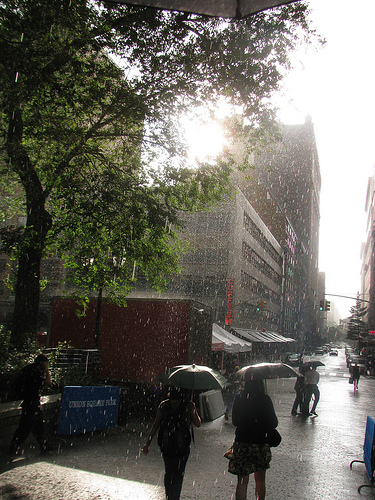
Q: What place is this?
A: It is a sidewalk.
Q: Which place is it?
A: It is a sidewalk.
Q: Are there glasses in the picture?
A: No, there are no glasses.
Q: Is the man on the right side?
A: Yes, the man is on the right of the image.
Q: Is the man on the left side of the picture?
A: No, the man is on the right of the image.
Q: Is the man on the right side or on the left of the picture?
A: The man is on the right of the image.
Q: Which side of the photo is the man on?
A: The man is on the right of the image.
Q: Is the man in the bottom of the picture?
A: Yes, the man is in the bottom of the image.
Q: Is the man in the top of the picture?
A: No, the man is in the bottom of the image.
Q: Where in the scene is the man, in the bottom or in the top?
A: The man is in the bottom of the image.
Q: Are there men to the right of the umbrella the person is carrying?
A: Yes, there is a man to the right of the umbrella.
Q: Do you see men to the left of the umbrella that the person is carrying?
A: No, the man is to the right of the umbrella.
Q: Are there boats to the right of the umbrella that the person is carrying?
A: No, there is a man to the right of the umbrella.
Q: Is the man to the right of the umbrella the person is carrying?
A: Yes, the man is to the right of the umbrella.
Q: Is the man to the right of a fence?
A: No, the man is to the right of the umbrella.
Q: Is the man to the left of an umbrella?
A: No, the man is to the right of an umbrella.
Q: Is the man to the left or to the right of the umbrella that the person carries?
A: The man is to the right of the umbrella.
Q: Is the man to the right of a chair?
A: No, the man is to the right of the umbrella.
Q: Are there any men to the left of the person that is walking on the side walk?
A: Yes, there is a man to the left of the person.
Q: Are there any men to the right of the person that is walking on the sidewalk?
A: No, the man is to the left of the person.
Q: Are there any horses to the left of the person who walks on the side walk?
A: No, there is a man to the left of the person.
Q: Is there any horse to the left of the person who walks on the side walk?
A: No, there is a man to the left of the person.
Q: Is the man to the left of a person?
A: Yes, the man is to the left of a person.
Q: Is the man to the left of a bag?
A: No, the man is to the left of a person.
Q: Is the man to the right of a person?
A: No, the man is to the left of a person.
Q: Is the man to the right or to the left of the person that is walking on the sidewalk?
A: The man is to the left of the person.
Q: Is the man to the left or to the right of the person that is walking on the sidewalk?
A: The man is to the left of the person.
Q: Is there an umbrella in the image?
A: Yes, there is an umbrella.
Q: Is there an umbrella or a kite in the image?
A: Yes, there is an umbrella.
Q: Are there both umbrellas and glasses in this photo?
A: No, there is an umbrella but no glasses.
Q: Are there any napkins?
A: No, there are no napkins.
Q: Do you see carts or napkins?
A: No, there are no napkins or carts.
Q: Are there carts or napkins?
A: No, there are no napkins or carts.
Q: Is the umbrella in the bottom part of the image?
A: Yes, the umbrella is in the bottom of the image.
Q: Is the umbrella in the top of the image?
A: No, the umbrella is in the bottom of the image.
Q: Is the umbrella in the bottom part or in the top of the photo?
A: The umbrella is in the bottom of the image.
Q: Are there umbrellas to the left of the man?
A: Yes, there is an umbrella to the left of the man.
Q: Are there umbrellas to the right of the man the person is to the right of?
A: No, the umbrella is to the left of the man.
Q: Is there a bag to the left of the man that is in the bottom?
A: No, there is an umbrella to the left of the man.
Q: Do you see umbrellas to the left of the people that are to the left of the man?
A: Yes, there is an umbrella to the left of the people.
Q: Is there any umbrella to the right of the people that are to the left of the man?
A: No, the umbrella is to the left of the people.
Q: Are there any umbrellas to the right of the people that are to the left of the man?
A: No, the umbrella is to the left of the people.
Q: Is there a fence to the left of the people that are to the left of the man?
A: No, there is an umbrella to the left of the people.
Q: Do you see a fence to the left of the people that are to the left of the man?
A: No, there is an umbrella to the left of the people.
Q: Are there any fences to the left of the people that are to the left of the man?
A: No, there is an umbrella to the left of the people.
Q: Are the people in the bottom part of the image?
A: Yes, the people are in the bottom of the image.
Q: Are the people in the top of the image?
A: No, the people are in the bottom of the image.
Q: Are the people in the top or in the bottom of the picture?
A: The people are in the bottom of the image.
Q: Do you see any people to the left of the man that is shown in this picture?
A: Yes, there are people to the left of the man.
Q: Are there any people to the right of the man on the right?
A: No, the people are to the left of the man.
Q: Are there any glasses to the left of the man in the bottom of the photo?
A: No, there are people to the left of the man.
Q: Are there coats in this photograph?
A: Yes, there is a coat.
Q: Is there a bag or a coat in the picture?
A: Yes, there is a coat.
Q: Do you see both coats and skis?
A: No, there is a coat but no skis.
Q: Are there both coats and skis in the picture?
A: No, there is a coat but no skis.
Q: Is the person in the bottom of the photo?
A: Yes, the person is in the bottom of the image.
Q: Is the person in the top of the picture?
A: No, the person is in the bottom of the image.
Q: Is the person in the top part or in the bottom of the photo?
A: The person is in the bottom of the image.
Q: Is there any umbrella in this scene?
A: Yes, there is an umbrella.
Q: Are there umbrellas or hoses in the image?
A: Yes, there is an umbrella.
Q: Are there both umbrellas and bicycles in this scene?
A: No, there is an umbrella but no bicycles.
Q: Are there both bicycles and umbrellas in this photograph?
A: No, there is an umbrella but no bicycles.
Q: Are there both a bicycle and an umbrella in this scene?
A: No, there is an umbrella but no bicycles.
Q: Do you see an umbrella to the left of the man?
A: Yes, there is an umbrella to the left of the man.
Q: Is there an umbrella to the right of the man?
A: No, the umbrella is to the left of the man.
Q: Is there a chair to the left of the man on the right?
A: No, there is an umbrella to the left of the man.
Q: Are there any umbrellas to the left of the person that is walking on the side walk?
A: Yes, there is an umbrella to the left of the person.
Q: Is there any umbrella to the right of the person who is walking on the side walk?
A: No, the umbrella is to the left of the person.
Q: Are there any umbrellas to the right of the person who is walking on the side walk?
A: No, the umbrella is to the left of the person.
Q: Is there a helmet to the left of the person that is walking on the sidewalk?
A: No, there is an umbrella to the left of the person.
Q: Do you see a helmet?
A: No, there are no helmets.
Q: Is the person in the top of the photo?
A: No, the person is in the bottom of the image.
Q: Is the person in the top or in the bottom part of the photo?
A: The person is in the bottom of the image.